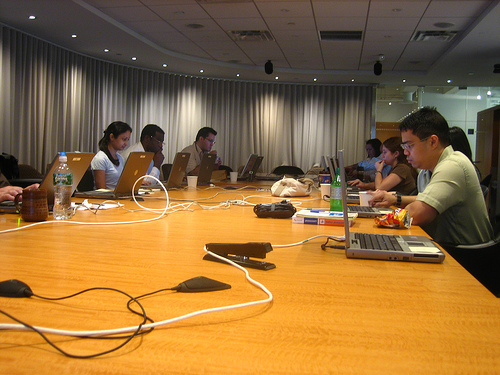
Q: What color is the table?
A: Brown.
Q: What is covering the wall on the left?
A: Curtain.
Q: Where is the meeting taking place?
A: Conference room.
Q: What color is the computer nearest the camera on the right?
A: Silver.